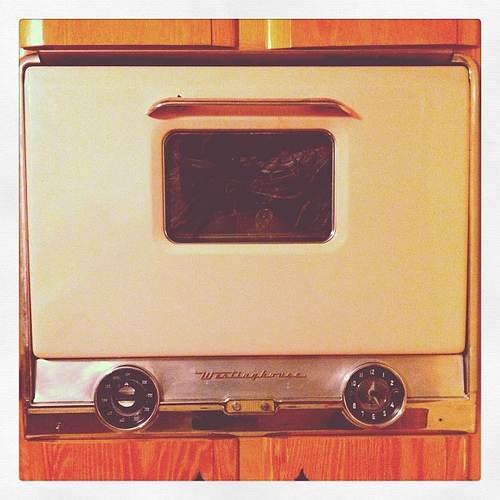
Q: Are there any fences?
A: No, there are no fences.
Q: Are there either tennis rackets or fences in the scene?
A: No, there are no fences or tennis rackets.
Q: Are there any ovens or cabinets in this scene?
A: Yes, there is a cabinet.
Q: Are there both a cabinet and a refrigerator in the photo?
A: No, there is a cabinet but no refrigerators.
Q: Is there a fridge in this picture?
A: No, there are no refrigerators.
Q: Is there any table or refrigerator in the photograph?
A: No, there are no refrigerators or tables.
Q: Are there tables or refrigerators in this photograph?
A: No, there are no refrigerators or tables.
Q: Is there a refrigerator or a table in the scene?
A: No, there are no refrigerators or tables.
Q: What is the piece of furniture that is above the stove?
A: The piece of furniture is a cabinet.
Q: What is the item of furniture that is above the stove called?
A: The piece of furniture is a cabinet.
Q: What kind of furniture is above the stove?
A: The piece of furniture is a cabinet.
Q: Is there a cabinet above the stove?
A: Yes, there is a cabinet above the stove.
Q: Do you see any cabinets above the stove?
A: Yes, there is a cabinet above the stove.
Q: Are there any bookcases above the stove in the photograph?
A: No, there is a cabinet above the stove.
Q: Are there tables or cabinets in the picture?
A: Yes, there is a cabinet.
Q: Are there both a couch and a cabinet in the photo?
A: No, there is a cabinet but no couches.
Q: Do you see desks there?
A: No, there are no desks.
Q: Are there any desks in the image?
A: No, there are no desks.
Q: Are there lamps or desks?
A: No, there are no desks or lamps.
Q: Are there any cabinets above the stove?
A: Yes, there is a cabinet above the stove.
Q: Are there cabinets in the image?
A: Yes, there is a cabinet.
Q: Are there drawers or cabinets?
A: Yes, there is a cabinet.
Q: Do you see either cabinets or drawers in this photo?
A: Yes, there is a cabinet.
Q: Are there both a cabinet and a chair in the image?
A: No, there is a cabinet but no chairs.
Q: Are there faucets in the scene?
A: No, there are no faucets.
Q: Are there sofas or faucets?
A: No, there are no faucets or sofas.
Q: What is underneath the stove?
A: The cabinet is underneath the stove.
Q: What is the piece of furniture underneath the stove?
A: The piece of furniture is a cabinet.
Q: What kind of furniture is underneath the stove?
A: The piece of furniture is a cabinet.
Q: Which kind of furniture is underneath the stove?
A: The piece of furniture is a cabinet.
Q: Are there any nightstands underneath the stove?
A: No, there is a cabinet underneath the stove.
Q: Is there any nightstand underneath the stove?
A: No, there is a cabinet underneath the stove.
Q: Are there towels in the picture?
A: No, there are no towels.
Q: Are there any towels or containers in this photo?
A: No, there are no towels or containers.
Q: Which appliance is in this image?
A: The appliance is a stove.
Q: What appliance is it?
A: The appliance is a stove.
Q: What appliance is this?
A: This is a stove.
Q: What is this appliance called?
A: This is a stove.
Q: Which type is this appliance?
A: This is a stove.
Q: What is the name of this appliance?
A: This is a stove.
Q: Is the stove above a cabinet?
A: Yes, the stove is above a cabinet.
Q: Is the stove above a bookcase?
A: No, the stove is above a cabinet.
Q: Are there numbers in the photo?
A: Yes, there are numbers.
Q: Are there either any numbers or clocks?
A: Yes, there are numbers.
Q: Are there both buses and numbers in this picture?
A: No, there are numbers but no buses.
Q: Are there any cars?
A: No, there are no cars.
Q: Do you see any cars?
A: No, there are no cars.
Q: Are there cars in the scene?
A: No, there are no cars.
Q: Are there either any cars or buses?
A: No, there are no cars or buses.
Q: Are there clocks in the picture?
A: Yes, there is a clock.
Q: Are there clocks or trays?
A: Yes, there is a clock.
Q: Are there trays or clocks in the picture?
A: Yes, there is a clock.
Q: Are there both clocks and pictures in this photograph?
A: No, there is a clock but no pictures.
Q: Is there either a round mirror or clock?
A: Yes, there is a round clock.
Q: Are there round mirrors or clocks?
A: Yes, there is a round clock.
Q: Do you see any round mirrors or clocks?
A: Yes, there is a round clock.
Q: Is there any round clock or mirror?
A: Yes, there is a round clock.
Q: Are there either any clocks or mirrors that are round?
A: Yes, the clock is round.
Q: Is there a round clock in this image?
A: Yes, there is a round clock.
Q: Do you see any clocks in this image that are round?
A: Yes, there is a clock that is round.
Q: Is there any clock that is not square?
A: Yes, there is a round clock.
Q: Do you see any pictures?
A: No, there are no pictures.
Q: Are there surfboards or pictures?
A: No, there are no pictures or surfboards.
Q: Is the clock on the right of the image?
A: Yes, the clock is on the right of the image.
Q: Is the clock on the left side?
A: No, the clock is on the right of the image.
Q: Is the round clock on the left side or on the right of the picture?
A: The clock is on the right of the image.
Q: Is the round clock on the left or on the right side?
A: The clock is on the right of the image.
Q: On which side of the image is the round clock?
A: The clock is on the right of the image.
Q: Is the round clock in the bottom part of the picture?
A: Yes, the clock is in the bottom of the image.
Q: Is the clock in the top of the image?
A: No, the clock is in the bottom of the image.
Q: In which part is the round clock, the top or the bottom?
A: The clock is in the bottom of the image.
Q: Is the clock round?
A: Yes, the clock is round.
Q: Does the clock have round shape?
A: Yes, the clock is round.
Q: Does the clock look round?
A: Yes, the clock is round.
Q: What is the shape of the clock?
A: The clock is round.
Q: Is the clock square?
A: No, the clock is round.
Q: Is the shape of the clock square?
A: No, the clock is round.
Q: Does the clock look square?
A: No, the clock is round.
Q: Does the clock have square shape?
A: No, the clock is round.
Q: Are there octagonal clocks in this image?
A: No, there is a clock but it is round.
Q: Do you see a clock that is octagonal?
A: No, there is a clock but it is round.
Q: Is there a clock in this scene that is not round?
A: No, there is a clock but it is round.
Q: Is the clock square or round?
A: The clock is round.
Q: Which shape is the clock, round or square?
A: The clock is round.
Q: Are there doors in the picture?
A: Yes, there is a door.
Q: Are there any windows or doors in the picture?
A: Yes, there is a door.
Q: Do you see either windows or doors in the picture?
A: Yes, there is a door.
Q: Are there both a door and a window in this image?
A: Yes, there are both a door and a window.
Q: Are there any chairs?
A: No, there are no chairs.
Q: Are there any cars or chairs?
A: No, there are no chairs or cars.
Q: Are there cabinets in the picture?
A: Yes, there is a cabinet.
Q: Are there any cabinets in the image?
A: Yes, there is a cabinet.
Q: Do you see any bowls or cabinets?
A: Yes, there is a cabinet.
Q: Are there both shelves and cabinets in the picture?
A: No, there is a cabinet but no shelves.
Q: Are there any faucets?
A: No, there are no faucets.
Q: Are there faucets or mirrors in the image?
A: No, there are no faucets or mirrors.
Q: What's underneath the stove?
A: The cabinet is underneath the stove.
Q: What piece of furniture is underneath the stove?
A: The piece of furniture is a cabinet.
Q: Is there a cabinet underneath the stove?
A: Yes, there is a cabinet underneath the stove.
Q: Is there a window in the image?
A: Yes, there is a window.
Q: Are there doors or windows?
A: Yes, there is a window.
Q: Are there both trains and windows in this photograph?
A: No, there is a window but no trains.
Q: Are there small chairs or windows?
A: Yes, there is a small window.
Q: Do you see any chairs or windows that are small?
A: Yes, the window is small.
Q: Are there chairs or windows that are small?
A: Yes, the window is small.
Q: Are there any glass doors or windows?
A: Yes, there is a glass window.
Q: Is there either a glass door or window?
A: Yes, there is a glass window.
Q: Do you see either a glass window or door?
A: Yes, there is a glass window.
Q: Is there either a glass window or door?
A: Yes, there is a glass window.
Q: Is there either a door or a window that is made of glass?
A: Yes, the window is made of glass.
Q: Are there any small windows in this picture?
A: Yes, there is a small window.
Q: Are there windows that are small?
A: Yes, there is a window that is small.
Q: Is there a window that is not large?
A: Yes, there is a small window.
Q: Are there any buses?
A: No, there are no buses.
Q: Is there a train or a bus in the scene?
A: No, there are no buses or trains.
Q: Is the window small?
A: Yes, the window is small.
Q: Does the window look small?
A: Yes, the window is small.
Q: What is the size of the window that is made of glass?
A: The window is small.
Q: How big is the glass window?
A: The window is small.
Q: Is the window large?
A: No, the window is small.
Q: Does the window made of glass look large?
A: No, the window is small.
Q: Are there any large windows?
A: No, there is a window but it is small.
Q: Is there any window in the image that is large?
A: No, there is a window but it is small.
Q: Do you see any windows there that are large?
A: No, there is a window but it is small.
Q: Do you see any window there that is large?
A: No, there is a window but it is small.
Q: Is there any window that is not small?
A: No, there is a window but it is small.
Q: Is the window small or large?
A: The window is small.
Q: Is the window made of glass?
A: Yes, the window is made of glass.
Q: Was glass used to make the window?
A: Yes, the window is made of glass.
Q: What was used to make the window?
A: The window is made of glass.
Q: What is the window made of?
A: The window is made of glass.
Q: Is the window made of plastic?
A: No, the window is made of glass.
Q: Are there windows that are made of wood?
A: No, there is a window but it is made of glass.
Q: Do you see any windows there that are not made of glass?
A: No, there is a window but it is made of glass.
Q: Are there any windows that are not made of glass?
A: No, there is a window but it is made of glass.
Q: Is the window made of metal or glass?
A: The window is made of glass.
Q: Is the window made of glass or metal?
A: The window is made of glass.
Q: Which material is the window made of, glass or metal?
A: The window is made of glass.